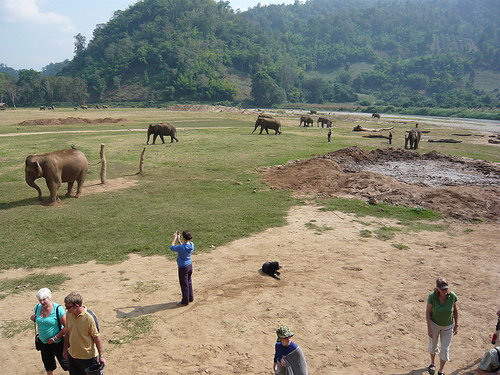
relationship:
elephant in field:
[145, 123, 181, 143] [0, 109, 498, 375]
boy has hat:
[273, 325, 308, 373] [277, 326, 295, 339]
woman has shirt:
[425, 278, 458, 375] [426, 290, 458, 327]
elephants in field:
[253, 114, 334, 135] [0, 109, 498, 375]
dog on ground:
[260, 261, 284, 280] [67, 263, 499, 375]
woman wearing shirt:
[171, 230, 195, 307] [171, 242, 194, 267]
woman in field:
[29, 287, 67, 374] [0, 109, 498, 375]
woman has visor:
[425, 278, 458, 375] [435, 278, 449, 290]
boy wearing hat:
[273, 325, 308, 373] [277, 326, 295, 339]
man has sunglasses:
[60, 293, 107, 375] [65, 305, 77, 309]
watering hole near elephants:
[283, 146, 499, 214] [253, 114, 334, 135]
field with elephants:
[0, 109, 498, 375] [253, 114, 334, 135]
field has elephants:
[0, 109, 498, 375] [253, 114, 334, 135]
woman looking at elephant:
[171, 230, 195, 307] [24, 150, 87, 207]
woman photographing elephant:
[171, 230, 195, 307] [145, 123, 181, 143]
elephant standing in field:
[24, 150, 87, 207] [0, 109, 498, 375]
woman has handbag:
[29, 287, 67, 374] [35, 335, 41, 352]